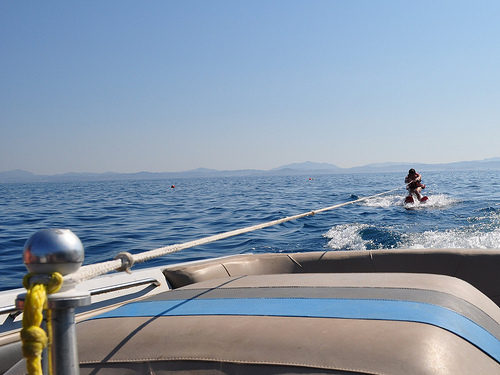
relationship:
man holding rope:
[400, 167, 430, 208] [23, 182, 436, 277]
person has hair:
[400, 167, 430, 208] [407, 168, 415, 174]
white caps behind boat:
[325, 221, 492, 250] [5, 250, 500, 374]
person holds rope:
[400, 167, 430, 208] [23, 182, 436, 277]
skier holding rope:
[400, 167, 430, 208] [23, 182, 436, 277]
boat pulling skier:
[5, 250, 500, 374] [400, 167, 430, 208]